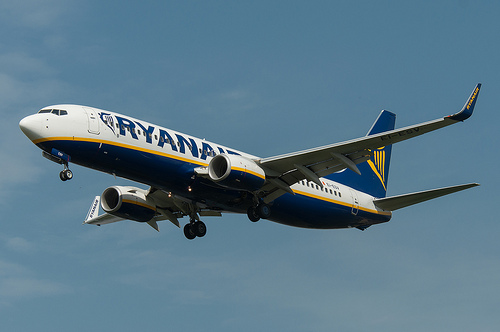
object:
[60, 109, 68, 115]
windows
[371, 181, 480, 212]
horizontal stabilizer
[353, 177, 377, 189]
blue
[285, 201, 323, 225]
blue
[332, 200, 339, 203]
yellow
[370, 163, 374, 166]
yellow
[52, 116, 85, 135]
white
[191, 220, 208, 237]
wheel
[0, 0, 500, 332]
sky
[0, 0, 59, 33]
cloud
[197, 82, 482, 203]
wing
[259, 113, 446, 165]
edge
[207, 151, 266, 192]
jet engine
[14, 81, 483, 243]
airplane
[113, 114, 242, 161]
lettering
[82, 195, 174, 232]
wing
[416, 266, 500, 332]
cloud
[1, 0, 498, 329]
bluesky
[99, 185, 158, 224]
engine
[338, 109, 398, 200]
tail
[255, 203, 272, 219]
wheel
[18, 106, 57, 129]
nose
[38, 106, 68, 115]
cockpit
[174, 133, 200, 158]
writings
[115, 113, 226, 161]
writing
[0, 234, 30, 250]
clouds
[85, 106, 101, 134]
door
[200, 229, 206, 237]
part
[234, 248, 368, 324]
part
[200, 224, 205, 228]
part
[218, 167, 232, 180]
part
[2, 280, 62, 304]
part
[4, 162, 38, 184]
part